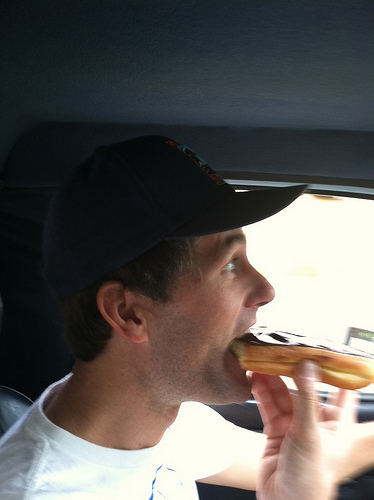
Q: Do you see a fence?
A: No, there are no fences.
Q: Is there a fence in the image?
A: No, there are no fences.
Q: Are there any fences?
A: No, there are no fences.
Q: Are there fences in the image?
A: No, there are no fences.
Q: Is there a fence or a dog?
A: No, there are no fences or dogs.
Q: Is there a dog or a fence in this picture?
A: No, there are no fences or dogs.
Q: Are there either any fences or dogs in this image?
A: No, there are no fences or dogs.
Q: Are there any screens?
A: No, there are no screens.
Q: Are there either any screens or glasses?
A: No, there are no screens or glasses.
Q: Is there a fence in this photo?
A: No, there are no fences.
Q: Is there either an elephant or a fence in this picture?
A: No, there are no fences or elephants.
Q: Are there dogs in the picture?
A: No, there are no dogs.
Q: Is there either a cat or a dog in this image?
A: No, there are no dogs or cats.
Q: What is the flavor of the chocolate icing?
A: This is a chocolate icing.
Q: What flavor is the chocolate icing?
A: This is a chocolate icing.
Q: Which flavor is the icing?
A: This is a chocolate icing.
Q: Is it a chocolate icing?
A: Yes, this is a chocolate icing.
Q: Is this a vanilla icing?
A: No, this is a chocolate icing.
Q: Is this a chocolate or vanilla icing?
A: This is a chocolate icing.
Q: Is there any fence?
A: No, there are no fences.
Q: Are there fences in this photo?
A: No, there are no fences.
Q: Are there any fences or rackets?
A: No, there are no fences or rackets.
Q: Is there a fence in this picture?
A: No, there are no fences.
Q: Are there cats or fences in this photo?
A: No, there are no fences or cats.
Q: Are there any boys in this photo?
A: No, there are no boys.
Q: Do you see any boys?
A: No, there are no boys.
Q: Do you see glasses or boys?
A: No, there are no boys or glasses.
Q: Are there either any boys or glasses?
A: No, there are no boys or glasses.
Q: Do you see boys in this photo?
A: No, there are no boys.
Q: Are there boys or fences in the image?
A: No, there are no boys or fences.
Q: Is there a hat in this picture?
A: Yes, there is a hat.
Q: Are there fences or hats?
A: Yes, there is a hat.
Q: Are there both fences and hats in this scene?
A: No, there is a hat but no fences.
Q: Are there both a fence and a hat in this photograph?
A: No, there is a hat but no fences.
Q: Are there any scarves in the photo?
A: No, there are no scarves.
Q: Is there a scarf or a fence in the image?
A: No, there are no scarves or fences.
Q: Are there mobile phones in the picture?
A: No, there are no mobile phones.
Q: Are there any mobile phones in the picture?
A: No, there are no mobile phones.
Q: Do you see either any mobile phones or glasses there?
A: No, there are no mobile phones or glasses.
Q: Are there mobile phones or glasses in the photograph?
A: No, there are no mobile phones or glasses.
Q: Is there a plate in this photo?
A: No, there are no plates.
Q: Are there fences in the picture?
A: No, there are no fences.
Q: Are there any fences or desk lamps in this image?
A: No, there are no fences or desk lamps.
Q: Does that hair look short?
A: Yes, the hair is short.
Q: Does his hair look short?
A: Yes, the hair is short.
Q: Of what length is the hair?
A: The hair is short.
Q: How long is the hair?
A: The hair is short.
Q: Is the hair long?
A: No, the hair is short.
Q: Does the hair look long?
A: No, the hair is short.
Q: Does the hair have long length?
A: No, the hair is short.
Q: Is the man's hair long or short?
A: The hair is short.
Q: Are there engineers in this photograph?
A: No, there are no engineers.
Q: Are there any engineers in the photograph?
A: No, there are no engineers.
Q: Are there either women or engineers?
A: No, there are no engineers or women.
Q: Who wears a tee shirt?
A: The man wears a tee shirt.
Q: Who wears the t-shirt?
A: The man wears a tee shirt.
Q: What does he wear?
A: The man wears a tshirt.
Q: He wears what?
A: The man wears a tshirt.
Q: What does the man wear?
A: The man wears a tshirt.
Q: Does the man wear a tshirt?
A: Yes, the man wears a tshirt.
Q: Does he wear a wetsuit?
A: No, the man wears a tshirt.